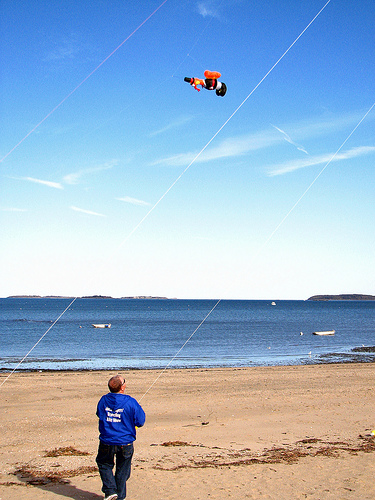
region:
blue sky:
[33, 34, 374, 307]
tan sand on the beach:
[26, 368, 374, 491]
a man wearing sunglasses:
[72, 370, 182, 495]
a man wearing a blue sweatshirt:
[73, 371, 186, 484]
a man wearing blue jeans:
[77, 368, 175, 499]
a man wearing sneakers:
[87, 364, 177, 497]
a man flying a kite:
[70, 25, 312, 499]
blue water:
[22, 280, 373, 379]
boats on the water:
[37, 295, 368, 386]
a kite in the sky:
[142, 36, 304, 143]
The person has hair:
[99, 370, 132, 393]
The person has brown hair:
[94, 368, 145, 411]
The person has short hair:
[97, 362, 138, 402]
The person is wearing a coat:
[86, 386, 150, 444]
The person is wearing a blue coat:
[85, 386, 158, 443]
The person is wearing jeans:
[65, 411, 156, 483]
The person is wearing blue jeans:
[75, 445, 165, 493]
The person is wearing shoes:
[94, 491, 136, 498]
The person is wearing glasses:
[112, 366, 129, 386]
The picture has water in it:
[131, 316, 370, 350]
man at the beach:
[98, 358, 160, 467]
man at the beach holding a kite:
[90, 371, 170, 497]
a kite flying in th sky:
[156, 39, 252, 117]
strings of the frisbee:
[10, 120, 284, 374]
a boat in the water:
[292, 317, 341, 340]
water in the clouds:
[38, 166, 267, 236]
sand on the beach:
[214, 384, 358, 487]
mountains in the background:
[41, 275, 158, 321]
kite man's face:
[106, 371, 138, 390]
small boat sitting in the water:
[77, 315, 144, 346]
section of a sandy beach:
[263, 386, 306, 410]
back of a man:
[109, 411, 124, 427]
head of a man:
[111, 380, 120, 387]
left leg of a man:
[103, 448, 112, 474]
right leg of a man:
[121, 448, 129, 481]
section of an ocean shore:
[227, 365, 291, 370]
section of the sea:
[126, 313, 156, 321]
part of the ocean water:
[285, 305, 315, 318]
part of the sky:
[210, 166, 263, 215]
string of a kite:
[248, 254, 255, 266]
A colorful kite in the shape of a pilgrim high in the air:
[166, 62, 243, 106]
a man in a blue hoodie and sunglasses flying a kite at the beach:
[85, 370, 156, 498]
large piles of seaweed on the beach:
[168, 437, 306, 475]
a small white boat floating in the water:
[310, 327, 345, 340]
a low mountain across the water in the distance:
[310, 292, 372, 309]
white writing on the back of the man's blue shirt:
[103, 406, 122, 425]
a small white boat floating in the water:
[86, 320, 117, 332]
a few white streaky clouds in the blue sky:
[257, 125, 371, 176]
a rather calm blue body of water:
[124, 318, 172, 351]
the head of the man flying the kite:
[104, 373, 129, 394]